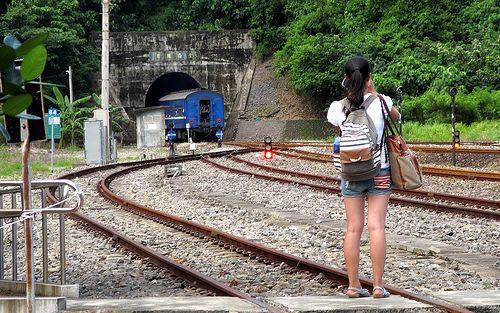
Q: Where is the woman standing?
A: Between train tracks.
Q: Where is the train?
A: In the tunnel.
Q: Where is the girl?
A: On the tracks.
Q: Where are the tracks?
A: On the gravel.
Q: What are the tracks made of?
A: Metal.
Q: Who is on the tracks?
A: The girl.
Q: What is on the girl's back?
A: A backpack.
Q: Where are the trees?
A: Next to the field.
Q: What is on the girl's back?
A: Backpack.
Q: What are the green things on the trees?
A: Leaves.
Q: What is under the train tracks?
A: Gravel.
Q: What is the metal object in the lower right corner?
A: Fence.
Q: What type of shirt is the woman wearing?
A: T shirt.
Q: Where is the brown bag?
A: Woman's right shoulder.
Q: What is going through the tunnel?
A: Train.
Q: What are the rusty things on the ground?
A: Tracks.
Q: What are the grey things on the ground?
A: Gravel.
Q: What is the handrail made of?
A: Metal.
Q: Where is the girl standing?
A: On the railroad tracks.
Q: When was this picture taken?
A: The daytime.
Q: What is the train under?
A: A tunnel.